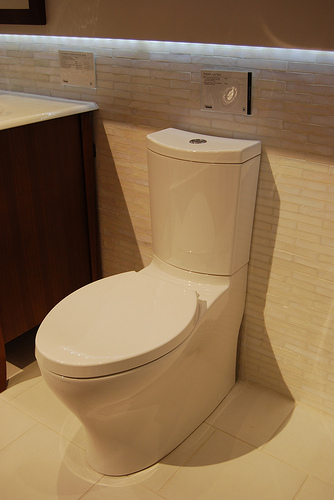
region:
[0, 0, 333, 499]
A toilet is in the bathroom.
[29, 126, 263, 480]
The toilet is white.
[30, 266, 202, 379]
The toilet seat is closed.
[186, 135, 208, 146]
A silver circle is on top of the toilet.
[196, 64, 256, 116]
A small sign is above the toilet.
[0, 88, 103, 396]
A bathroom counter is next to the toilet.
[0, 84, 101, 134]
The countertop is white.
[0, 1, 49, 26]
A picture frame is above the counter.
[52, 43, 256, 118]
Two small signs are on the wall.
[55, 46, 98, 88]
A small sign is next to the counter.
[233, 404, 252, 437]
part of a floor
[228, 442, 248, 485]
part of a loije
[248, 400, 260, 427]
part of a shade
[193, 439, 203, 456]
par tof a line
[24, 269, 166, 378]
this is a toilet cover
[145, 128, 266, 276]
this is a toilet water trunk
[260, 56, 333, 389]
this is a wall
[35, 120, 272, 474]
this is a toilet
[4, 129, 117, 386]
this is a cupboard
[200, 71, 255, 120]
this is a metal box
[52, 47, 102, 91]
this is a metal box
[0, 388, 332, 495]
these are tiles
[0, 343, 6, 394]
this is a cupbord leg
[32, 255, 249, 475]
a white porcelain toilet bowl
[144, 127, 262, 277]
a white porcelain toilet tank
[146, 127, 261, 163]
a white porcelain toilet tank lid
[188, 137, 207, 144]
a chrome toilet flush valve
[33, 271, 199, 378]
a white plastic toilet seat lid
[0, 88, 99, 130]
a white sink top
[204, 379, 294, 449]
a white floor tile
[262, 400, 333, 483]
a white floor tile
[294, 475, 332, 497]
a white floor tile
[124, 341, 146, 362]
edge of a line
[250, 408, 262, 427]
part of a shade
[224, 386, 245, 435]
part of a floor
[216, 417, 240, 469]
part of a floor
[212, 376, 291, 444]
a tile in a floor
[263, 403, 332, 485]
a tile in a floor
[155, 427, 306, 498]
a tile in a floor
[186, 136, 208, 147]
Silver button used to flush the toilet.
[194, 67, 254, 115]
Sign above the toilet on the wall.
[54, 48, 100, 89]
Sign above the counter on the wall.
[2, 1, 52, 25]
Edge of a picture above the counter.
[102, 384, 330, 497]
Floor tiles to the right of the toilet.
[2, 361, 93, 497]
Floor tiles to the left of the toilet.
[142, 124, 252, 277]
Top tank of the toilet that holds water.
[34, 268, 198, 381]
Lid on the toilet that has a hinge.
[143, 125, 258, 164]
Lid with a silver button that can be removed.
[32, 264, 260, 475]
Bottom of a toilet with no tank.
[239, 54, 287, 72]
a brick in a wall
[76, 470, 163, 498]
a tile in a floor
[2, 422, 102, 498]
a tile in a floor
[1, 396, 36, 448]
a tile in a floor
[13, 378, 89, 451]
a tile in a floor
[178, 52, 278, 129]
sign above the white toilet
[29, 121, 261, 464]
white toilet in the bathroom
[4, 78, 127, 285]
part of the bathroom sink against the wall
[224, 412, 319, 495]
white tile floor in the bathroom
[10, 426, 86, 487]
white tile floor in the bathroom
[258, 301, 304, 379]
tile wall behind the toilet